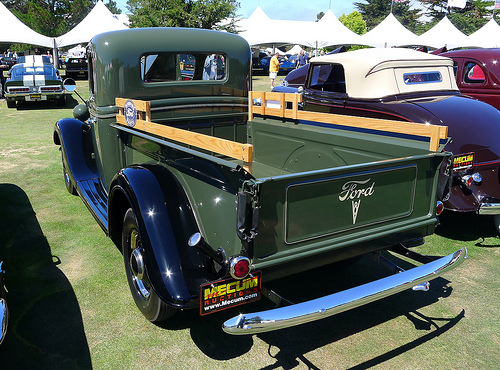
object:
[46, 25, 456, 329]
truck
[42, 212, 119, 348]
grass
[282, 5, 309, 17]
sky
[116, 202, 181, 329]
wheel